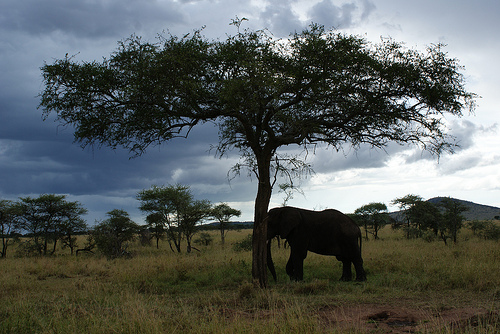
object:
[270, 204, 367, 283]
elephant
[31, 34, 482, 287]
tree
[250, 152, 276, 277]
trunk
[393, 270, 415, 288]
grass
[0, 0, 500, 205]
clouds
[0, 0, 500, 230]
sky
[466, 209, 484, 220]
hill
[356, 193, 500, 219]
distance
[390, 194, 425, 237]
tree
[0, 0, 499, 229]
background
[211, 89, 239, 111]
leaf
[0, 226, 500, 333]
heat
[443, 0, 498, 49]
cloud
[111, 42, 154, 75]
branches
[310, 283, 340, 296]
ground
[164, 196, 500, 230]
mountain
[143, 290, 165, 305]
dirt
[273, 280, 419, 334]
field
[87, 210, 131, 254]
bush